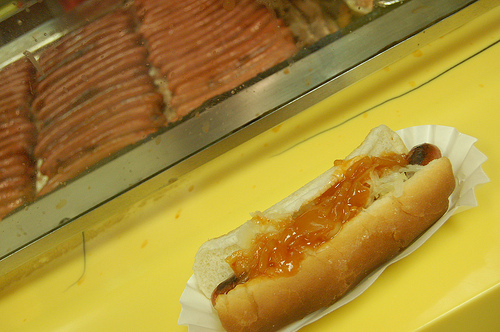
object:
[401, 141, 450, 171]
tip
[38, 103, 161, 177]
hotdog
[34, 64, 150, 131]
hotdog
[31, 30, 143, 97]
hotdog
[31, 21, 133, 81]
hotdog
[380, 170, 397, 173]
onions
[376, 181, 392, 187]
onions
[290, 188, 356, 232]
sourkraut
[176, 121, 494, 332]
holder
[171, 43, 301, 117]
dogs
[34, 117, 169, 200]
hot dogs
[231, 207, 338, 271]
ketchup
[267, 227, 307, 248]
sauce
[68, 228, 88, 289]
crack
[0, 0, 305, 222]
hot dog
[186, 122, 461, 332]
hotdog bun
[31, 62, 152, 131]
hot dogs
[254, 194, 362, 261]
sauerkraut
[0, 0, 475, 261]
display case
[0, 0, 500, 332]
counter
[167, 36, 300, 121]
hot dogs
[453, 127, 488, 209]
paper wrap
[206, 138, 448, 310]
hot dog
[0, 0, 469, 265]
grill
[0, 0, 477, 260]
warmer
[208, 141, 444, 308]
weiner